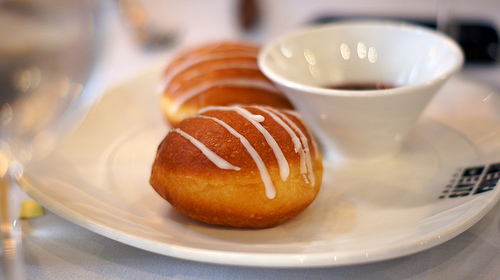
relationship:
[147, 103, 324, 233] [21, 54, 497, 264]
treat on top of plate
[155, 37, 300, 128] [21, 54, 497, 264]
treat on top of plate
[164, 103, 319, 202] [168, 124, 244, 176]
stripes of frosting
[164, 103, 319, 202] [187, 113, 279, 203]
stripes of frosting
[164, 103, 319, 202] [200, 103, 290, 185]
stripes of frosting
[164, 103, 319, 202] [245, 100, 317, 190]
stripes of frosting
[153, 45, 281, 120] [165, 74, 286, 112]
stripes of frosting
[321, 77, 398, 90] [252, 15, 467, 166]
liquid in bowl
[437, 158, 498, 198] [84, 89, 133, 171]
writing on plate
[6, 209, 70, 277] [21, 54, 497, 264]
white table beneath plate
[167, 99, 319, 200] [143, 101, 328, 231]
frosting on pastry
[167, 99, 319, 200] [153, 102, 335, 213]
frosting on pastry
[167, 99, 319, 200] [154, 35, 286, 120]
frosting on pastry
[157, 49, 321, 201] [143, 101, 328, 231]
frosting on pastry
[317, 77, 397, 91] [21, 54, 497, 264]
compote on plate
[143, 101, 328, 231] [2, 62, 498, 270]
pastry on plate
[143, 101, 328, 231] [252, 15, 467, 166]
pastry next to bowl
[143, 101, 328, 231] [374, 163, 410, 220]
pastry on dish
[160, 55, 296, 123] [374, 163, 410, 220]
pastry on dish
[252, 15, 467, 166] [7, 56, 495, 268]
bowl on dish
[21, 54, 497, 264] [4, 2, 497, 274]
plate on table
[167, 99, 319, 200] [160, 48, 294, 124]
frosting on pastry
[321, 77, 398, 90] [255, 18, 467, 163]
liquid in cup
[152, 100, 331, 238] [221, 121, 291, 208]
doughnut with icing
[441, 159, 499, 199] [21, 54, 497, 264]
logo on plate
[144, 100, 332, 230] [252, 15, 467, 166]
doughnut with bowl